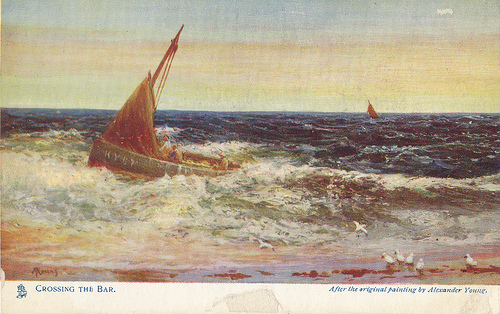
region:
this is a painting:
[24, 23, 409, 308]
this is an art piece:
[35, 31, 311, 243]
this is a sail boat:
[60, 37, 211, 199]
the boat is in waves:
[51, 137, 290, 264]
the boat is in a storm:
[22, 58, 350, 232]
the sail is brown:
[120, 101, 182, 161]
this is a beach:
[31, 234, 187, 311]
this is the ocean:
[245, 104, 427, 150]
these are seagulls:
[355, 232, 470, 279]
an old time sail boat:
[85, 18, 256, 193]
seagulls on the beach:
[371, 240, 484, 277]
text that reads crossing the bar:
[28, 274, 128, 298]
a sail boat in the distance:
[363, 95, 380, 125]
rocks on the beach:
[237, 257, 497, 281]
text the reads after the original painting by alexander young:
[327, 280, 492, 298]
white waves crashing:
[1, 123, 350, 255]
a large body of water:
[0, 80, 477, 186]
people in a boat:
[161, 132, 183, 157]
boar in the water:
[90, 23, 275, 174]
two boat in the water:
[84, 27, 396, 184]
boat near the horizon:
[358, 100, 388, 118]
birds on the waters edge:
[249, 216, 489, 274]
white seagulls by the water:
[248, 210, 486, 280]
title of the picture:
[37, 281, 122, 298]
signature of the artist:
[33, 260, 60, 280]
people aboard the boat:
[158, 134, 239, 176]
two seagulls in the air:
[258, 215, 375, 253]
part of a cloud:
[288, 135, 314, 199]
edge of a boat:
[183, 147, 197, 186]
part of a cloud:
[311, 90, 321, 106]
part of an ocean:
[275, 168, 278, 180]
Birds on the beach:
[374, 244, 481, 278]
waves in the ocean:
[238, 156, 463, 251]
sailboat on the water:
[87, 35, 237, 191]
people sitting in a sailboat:
[159, 130, 234, 172]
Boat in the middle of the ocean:
[354, 94, 388, 127]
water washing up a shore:
[61, 188, 280, 254]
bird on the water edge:
[342, 210, 478, 280]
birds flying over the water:
[235, 217, 380, 254]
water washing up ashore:
[125, 210, 272, 273]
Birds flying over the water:
[342, 207, 372, 242]